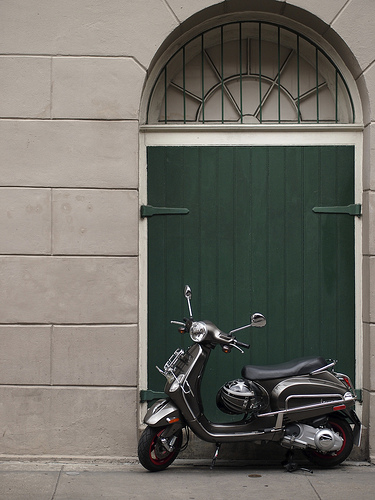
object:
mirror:
[250, 312, 267, 329]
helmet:
[215, 378, 266, 416]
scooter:
[137, 283, 361, 472]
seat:
[241, 355, 329, 380]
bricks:
[0, 255, 137, 322]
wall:
[1, 4, 137, 455]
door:
[146, 145, 355, 429]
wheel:
[138, 425, 184, 472]